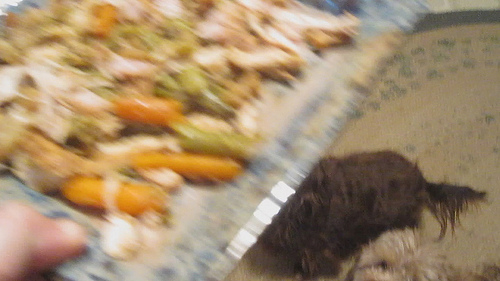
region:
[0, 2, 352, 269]
a pan full of food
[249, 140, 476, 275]
a dark brown dog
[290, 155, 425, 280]
a dog going under the tray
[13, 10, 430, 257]
a silver tray with food on it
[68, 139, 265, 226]
yellow chunks of food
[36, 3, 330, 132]
torn up pieces of meat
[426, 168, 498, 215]
a brown furry tail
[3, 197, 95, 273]
a finger on the tray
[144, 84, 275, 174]
green pieces of food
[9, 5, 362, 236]
a blurry picture of food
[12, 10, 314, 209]
blurry food on plate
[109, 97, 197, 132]
blurry carrot on plate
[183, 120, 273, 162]
blurry brocolli on plate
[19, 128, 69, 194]
blurry chicken on plate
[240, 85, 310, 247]
edge of silver plate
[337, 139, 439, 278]
something brown and tan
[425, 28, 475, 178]
tan and green rug on floor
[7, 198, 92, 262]
blurry food on a plate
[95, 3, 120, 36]
another blurry carrot on plate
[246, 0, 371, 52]
chicken on a plate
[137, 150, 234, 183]
Carrot on the tray.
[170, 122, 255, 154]
Green bean on the tray.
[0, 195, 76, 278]
Thumb on the end of the tray.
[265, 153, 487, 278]
Dark brown dog on floor.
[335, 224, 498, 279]
Tan colored dog on the floor.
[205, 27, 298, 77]
Cut up chicken on the tray.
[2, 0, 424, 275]
Silver serving tray.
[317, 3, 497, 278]
Oval rug on the floor.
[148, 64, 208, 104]
Broccoli on the tray.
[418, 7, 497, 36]
Blue edge on the rug.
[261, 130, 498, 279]
This is a rodent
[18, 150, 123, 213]
a piece of food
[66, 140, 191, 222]
a piece of food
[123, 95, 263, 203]
a piece of food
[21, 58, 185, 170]
a piece of food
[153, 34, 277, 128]
a piece of food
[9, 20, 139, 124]
a piece of food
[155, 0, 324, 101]
a piece of food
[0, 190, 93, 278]
Hand of a person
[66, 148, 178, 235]
A piece of food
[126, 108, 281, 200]
A piece of food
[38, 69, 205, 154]
A piece of food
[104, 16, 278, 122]
A piece of food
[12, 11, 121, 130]
A piece of food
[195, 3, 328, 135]
A piece of food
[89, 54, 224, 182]
A piece of food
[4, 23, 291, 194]
A piece of food